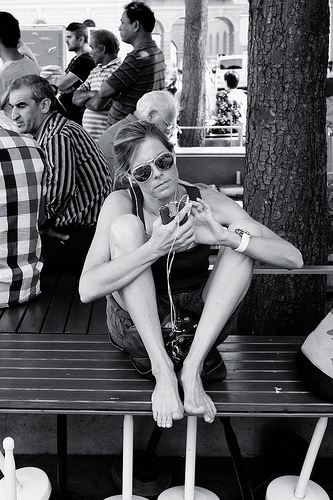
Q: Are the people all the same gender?
A: No, they are both male and female.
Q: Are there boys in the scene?
A: No, there are no boys.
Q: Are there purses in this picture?
A: Yes, there is a purse.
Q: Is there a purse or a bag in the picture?
A: Yes, there is a purse.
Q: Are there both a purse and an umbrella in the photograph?
A: No, there is a purse but no umbrellas.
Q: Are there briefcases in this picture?
A: No, there are no briefcases.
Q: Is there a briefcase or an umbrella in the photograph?
A: No, there are no briefcases or umbrellas.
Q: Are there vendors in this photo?
A: No, there are no vendors.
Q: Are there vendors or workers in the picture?
A: No, there are no vendors or workers.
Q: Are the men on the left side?
A: Yes, the men are on the left of the image.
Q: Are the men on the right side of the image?
A: No, the men are on the left of the image.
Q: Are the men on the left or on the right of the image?
A: The men are on the left of the image.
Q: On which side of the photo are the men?
A: The men are on the left of the image.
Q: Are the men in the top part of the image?
A: Yes, the men are in the top of the image.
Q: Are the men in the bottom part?
A: No, the men are in the top of the image.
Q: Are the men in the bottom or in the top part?
A: The men are in the top of the image.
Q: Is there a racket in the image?
A: No, there are no rackets.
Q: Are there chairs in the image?
A: No, there are no chairs.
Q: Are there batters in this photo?
A: No, there are no batters.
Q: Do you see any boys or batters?
A: No, there are no batters or boys.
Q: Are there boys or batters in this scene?
A: No, there are no batters or boys.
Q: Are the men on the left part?
A: Yes, the men are on the left of the image.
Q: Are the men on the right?
A: No, the men are on the left of the image.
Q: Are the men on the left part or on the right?
A: The men are on the left of the image.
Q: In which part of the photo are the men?
A: The men are on the left of the image.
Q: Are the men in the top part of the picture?
A: Yes, the men are in the top of the image.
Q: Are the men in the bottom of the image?
A: No, the men are in the top of the image.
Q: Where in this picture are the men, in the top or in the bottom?
A: The men are in the top of the image.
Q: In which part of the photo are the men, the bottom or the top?
A: The men are in the top of the image.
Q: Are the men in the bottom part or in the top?
A: The men are in the top of the image.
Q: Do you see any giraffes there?
A: No, there are no giraffes.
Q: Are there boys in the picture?
A: No, there are no boys.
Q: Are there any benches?
A: Yes, there is a bench.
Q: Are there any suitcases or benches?
A: Yes, there is a bench.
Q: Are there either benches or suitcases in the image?
A: Yes, there is a bench.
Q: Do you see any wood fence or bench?
A: Yes, there is a wood bench.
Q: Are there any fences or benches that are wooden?
A: Yes, the bench is wooden.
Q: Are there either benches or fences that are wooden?
A: Yes, the bench is wooden.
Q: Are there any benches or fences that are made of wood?
A: Yes, the bench is made of wood.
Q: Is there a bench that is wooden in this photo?
A: Yes, there is a wood bench.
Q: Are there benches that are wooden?
A: Yes, there is a bench that is wooden.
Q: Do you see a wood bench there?
A: Yes, there is a bench that is made of wood.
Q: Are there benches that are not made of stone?
A: Yes, there is a bench that is made of wood.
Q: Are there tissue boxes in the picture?
A: No, there are no tissue boxes.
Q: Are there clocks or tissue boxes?
A: No, there are no tissue boxes or clocks.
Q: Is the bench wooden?
A: Yes, the bench is wooden.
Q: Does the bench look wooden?
A: Yes, the bench is wooden.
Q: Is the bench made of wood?
A: Yes, the bench is made of wood.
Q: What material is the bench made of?
A: The bench is made of wood.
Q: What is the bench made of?
A: The bench is made of wood.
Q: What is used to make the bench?
A: The bench is made of wood.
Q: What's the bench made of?
A: The bench is made of wood.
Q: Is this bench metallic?
A: No, the bench is wooden.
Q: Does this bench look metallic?
A: No, the bench is wooden.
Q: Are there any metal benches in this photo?
A: No, there is a bench but it is made of wood.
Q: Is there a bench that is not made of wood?
A: No, there is a bench but it is made of wood.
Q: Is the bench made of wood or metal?
A: The bench is made of wood.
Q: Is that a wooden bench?
A: Yes, that is a wooden bench.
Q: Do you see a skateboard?
A: No, there are no skateboards.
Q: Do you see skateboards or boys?
A: No, there are no skateboards or boys.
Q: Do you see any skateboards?
A: No, there are no skateboards.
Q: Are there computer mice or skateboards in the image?
A: No, there are no skateboards or computer mice.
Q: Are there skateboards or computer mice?
A: No, there are no skateboards or computer mice.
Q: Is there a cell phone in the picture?
A: Yes, there is a cell phone.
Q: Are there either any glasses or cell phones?
A: Yes, there is a cell phone.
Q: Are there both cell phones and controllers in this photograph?
A: No, there is a cell phone but no controllers.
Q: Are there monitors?
A: No, there are no monitors.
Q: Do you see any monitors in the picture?
A: No, there are no monitors.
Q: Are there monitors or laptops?
A: No, there are no monitors or laptops.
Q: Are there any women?
A: Yes, there is a woman.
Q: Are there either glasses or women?
A: Yes, there is a woman.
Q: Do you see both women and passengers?
A: No, there is a woman but no passengers.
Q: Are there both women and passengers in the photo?
A: No, there is a woman but no passengers.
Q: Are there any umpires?
A: No, there are no umpires.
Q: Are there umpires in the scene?
A: No, there are no umpires.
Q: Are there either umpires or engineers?
A: No, there are no umpires or engineers.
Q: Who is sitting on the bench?
A: The woman is sitting on the bench.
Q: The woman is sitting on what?
A: The woman is sitting on the bench.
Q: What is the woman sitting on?
A: The woman is sitting on the bench.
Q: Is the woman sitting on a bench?
A: Yes, the woman is sitting on a bench.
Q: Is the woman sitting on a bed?
A: No, the woman is sitting on a bench.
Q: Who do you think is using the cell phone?
A: The woman is using the cell phone.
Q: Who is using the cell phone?
A: The woman is using the cell phone.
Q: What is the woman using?
A: The woman is using a mobile phone.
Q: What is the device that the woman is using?
A: The device is a cell phone.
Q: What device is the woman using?
A: The woman is using a mobile phone.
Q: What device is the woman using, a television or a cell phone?
A: The woman is using a cell phone.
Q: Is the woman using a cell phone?
A: Yes, the woman is using a cell phone.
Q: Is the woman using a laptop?
A: No, the woman is using a cell phone.